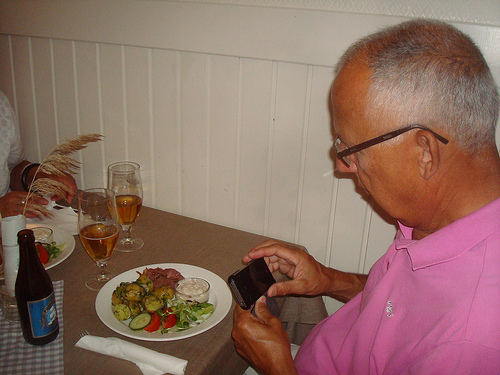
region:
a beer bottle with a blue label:
[16, 229, 58, 344]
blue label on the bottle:
[26, 293, 60, 335]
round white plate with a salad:
[104, 261, 234, 340]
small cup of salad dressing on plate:
[177, 279, 212, 304]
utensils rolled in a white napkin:
[73, 331, 186, 373]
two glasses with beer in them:
[77, 161, 142, 292]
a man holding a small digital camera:
[227, 16, 492, 371]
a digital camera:
[227, 256, 270, 311]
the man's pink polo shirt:
[292, 198, 499, 368]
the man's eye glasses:
[332, 123, 446, 162]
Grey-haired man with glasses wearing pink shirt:
[230, 20, 498, 372]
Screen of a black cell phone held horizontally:
[225, 255, 273, 306]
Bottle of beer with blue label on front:
[10, 225, 60, 341]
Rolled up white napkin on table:
[71, 330, 187, 373]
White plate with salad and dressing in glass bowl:
[90, 260, 230, 342]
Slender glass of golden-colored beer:
[75, 185, 118, 286]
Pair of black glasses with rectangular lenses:
[333, 123, 448, 168]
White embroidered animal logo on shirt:
[381, 301, 396, 320]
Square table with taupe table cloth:
[0, 188, 304, 373]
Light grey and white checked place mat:
[0, 276, 66, 373]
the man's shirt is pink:
[290, 207, 498, 372]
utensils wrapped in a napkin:
[75, 328, 201, 373]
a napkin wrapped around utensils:
[65, 325, 197, 374]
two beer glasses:
[58, 141, 156, 287]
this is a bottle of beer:
[7, 223, 72, 347]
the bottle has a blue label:
[25, 288, 67, 340]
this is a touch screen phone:
[217, 244, 286, 321]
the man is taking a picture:
[194, 5, 485, 371]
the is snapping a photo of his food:
[60, 0, 487, 372]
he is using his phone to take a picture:
[222, 4, 497, 355]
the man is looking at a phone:
[176, 3, 480, 358]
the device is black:
[205, 232, 297, 332]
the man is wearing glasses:
[272, 20, 459, 222]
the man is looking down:
[279, 9, 483, 245]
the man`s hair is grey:
[270, 9, 488, 203]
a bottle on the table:
[8, 200, 82, 366]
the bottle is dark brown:
[0, 219, 74, 352]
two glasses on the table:
[55, 132, 170, 260]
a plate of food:
[85, 247, 245, 349]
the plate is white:
[78, 235, 241, 362]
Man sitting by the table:
[230, 66, 497, 374]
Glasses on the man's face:
[332, 122, 449, 169]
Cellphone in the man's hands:
[227, 258, 277, 309]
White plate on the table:
[95, 262, 232, 342]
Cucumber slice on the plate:
[128, 312, 152, 330]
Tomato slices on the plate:
[145, 307, 177, 333]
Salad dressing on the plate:
[172, 277, 211, 304]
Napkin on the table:
[71, 332, 189, 374]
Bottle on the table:
[14, 229, 60, 346]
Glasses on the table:
[75, 159, 145, 289]